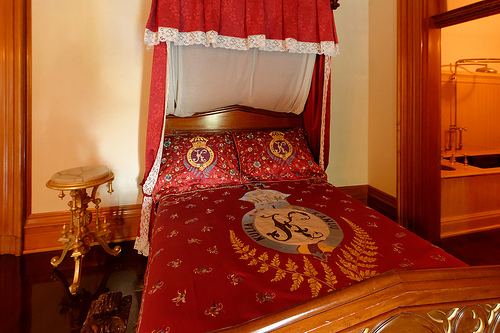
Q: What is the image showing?
A: It is showing a bedroom.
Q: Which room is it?
A: It is a bedroom.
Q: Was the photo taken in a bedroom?
A: Yes, it was taken in a bedroom.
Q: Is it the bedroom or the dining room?
A: It is the bedroom.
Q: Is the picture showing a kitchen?
A: No, the picture is showing a bedroom.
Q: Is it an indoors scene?
A: Yes, it is indoors.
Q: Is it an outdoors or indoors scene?
A: It is indoors.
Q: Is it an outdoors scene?
A: No, it is indoors.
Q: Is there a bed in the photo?
A: Yes, there is a bed.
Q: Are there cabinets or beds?
A: Yes, there is a bed.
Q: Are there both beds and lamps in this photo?
A: No, there is a bed but no lamps.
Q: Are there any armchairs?
A: No, there are no armchairs.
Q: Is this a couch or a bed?
A: This is a bed.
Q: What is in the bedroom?
A: The bed is in the bedroom.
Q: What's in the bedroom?
A: The bed is in the bedroom.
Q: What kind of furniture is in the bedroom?
A: The piece of furniture is a bed.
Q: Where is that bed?
A: The bed is in the bedroom.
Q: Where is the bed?
A: The bed is in the bedroom.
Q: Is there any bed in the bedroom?
A: Yes, there is a bed in the bedroom.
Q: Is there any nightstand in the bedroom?
A: No, there is a bed in the bedroom.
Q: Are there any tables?
A: Yes, there is a table.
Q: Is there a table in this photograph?
A: Yes, there is a table.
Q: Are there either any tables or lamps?
A: Yes, there is a table.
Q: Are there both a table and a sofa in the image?
A: No, there is a table but no sofas.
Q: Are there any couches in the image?
A: No, there are no couches.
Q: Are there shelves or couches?
A: No, there are no couches or shelves.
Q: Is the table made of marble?
A: Yes, the table is made of marble.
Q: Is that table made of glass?
A: No, the table is made of marble.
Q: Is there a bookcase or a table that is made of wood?
A: No, there is a table but it is made of marble.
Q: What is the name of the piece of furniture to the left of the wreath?
A: The piece of furniture is a table.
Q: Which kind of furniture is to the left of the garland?
A: The piece of furniture is a table.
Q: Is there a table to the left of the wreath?
A: Yes, there is a table to the left of the wreath.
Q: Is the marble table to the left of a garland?
A: Yes, the table is to the left of a garland.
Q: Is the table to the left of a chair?
A: No, the table is to the left of a garland.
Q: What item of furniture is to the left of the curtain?
A: The piece of furniture is a table.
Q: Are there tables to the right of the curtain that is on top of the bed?
A: No, the table is to the left of the curtain.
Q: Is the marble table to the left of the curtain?
A: Yes, the table is to the left of the curtain.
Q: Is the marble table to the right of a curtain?
A: No, the table is to the left of a curtain.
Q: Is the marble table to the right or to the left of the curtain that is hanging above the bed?
A: The table is to the left of the curtain.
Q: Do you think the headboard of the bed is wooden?
A: Yes, the headboard is wooden.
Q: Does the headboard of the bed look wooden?
A: Yes, the headboard is wooden.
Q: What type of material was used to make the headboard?
A: The headboard is made of wood.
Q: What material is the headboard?
A: The headboard is made of wood.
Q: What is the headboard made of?
A: The headboard is made of wood.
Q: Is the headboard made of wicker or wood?
A: The headboard is made of wood.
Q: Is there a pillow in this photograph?
A: Yes, there is a pillow.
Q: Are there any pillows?
A: Yes, there is a pillow.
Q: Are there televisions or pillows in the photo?
A: Yes, there is a pillow.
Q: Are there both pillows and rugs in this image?
A: No, there is a pillow but no rugs.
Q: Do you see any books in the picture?
A: No, there are no books.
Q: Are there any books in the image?
A: No, there are no books.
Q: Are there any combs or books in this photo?
A: No, there are no books or combs.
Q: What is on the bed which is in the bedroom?
A: The pillow is on the bed.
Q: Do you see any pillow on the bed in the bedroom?
A: Yes, there is a pillow on the bed.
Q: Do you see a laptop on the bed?
A: No, there is a pillow on the bed.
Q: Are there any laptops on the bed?
A: No, there is a pillow on the bed.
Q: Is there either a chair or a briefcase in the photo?
A: No, there are no chairs or briefcases.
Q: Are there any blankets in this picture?
A: Yes, there is a blanket.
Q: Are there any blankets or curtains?
A: Yes, there is a blanket.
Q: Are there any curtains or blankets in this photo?
A: Yes, there is a blanket.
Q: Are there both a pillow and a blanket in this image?
A: Yes, there are both a blanket and a pillow.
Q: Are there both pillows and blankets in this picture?
A: Yes, there are both a blanket and a pillow.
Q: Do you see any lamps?
A: No, there are no lamps.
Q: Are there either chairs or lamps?
A: No, there are no lamps or chairs.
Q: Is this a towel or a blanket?
A: This is a blanket.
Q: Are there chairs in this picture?
A: No, there are no chairs.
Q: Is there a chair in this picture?
A: No, there are no chairs.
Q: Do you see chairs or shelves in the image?
A: No, there are no chairs or shelves.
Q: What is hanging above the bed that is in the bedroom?
A: The curtain is hanging above the bed.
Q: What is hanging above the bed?
A: The curtain is hanging above the bed.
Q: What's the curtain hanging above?
A: The curtain is hanging above the bed.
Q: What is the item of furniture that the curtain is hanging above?
A: The piece of furniture is a bed.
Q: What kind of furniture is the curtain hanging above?
A: The curtain is hanging above the bed.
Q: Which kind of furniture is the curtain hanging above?
A: The curtain is hanging above the bed.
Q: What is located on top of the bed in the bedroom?
A: The curtain is on top of the bed.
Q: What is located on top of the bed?
A: The curtain is on top of the bed.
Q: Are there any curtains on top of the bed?
A: Yes, there is a curtain on top of the bed.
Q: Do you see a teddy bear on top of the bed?
A: No, there is a curtain on top of the bed.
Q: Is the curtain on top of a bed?
A: Yes, the curtain is on top of a bed.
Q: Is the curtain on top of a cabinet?
A: No, the curtain is on top of a bed.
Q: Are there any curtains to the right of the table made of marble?
A: Yes, there is a curtain to the right of the table.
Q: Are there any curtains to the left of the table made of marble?
A: No, the curtain is to the right of the table.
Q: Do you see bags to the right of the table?
A: No, there is a curtain to the right of the table.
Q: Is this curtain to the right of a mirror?
A: No, the curtain is to the right of the table.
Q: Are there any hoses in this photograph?
A: No, there are no hoses.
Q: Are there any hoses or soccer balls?
A: No, there are no hoses or soccer balls.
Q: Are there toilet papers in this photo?
A: No, there are no toilet papers.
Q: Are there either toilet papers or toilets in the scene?
A: No, there are no toilet papers or toilets.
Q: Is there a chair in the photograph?
A: No, there are no chairs.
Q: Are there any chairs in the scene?
A: No, there are no chairs.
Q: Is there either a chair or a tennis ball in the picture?
A: No, there are no chairs or tennis balls.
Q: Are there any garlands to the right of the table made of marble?
A: Yes, there is a garland to the right of the table.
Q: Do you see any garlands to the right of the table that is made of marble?
A: Yes, there is a garland to the right of the table.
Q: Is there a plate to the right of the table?
A: No, there is a garland to the right of the table.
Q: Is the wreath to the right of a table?
A: Yes, the wreath is to the right of a table.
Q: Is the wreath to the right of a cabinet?
A: No, the wreath is to the right of a table.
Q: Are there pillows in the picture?
A: Yes, there is a pillow.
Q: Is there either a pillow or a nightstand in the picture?
A: Yes, there is a pillow.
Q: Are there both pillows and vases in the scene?
A: No, there is a pillow but no vases.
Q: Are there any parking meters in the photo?
A: No, there are no parking meters.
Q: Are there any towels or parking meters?
A: No, there are no parking meters or towels.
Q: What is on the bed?
A: The pillow is on the bed.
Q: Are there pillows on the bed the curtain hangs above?
A: Yes, there is a pillow on the bed.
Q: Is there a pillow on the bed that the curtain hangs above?
A: Yes, there is a pillow on the bed.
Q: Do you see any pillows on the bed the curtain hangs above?
A: Yes, there is a pillow on the bed.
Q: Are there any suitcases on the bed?
A: No, there is a pillow on the bed.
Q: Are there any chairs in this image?
A: No, there are no chairs.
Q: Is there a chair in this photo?
A: No, there are no chairs.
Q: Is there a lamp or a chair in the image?
A: No, there are no chairs or lamps.